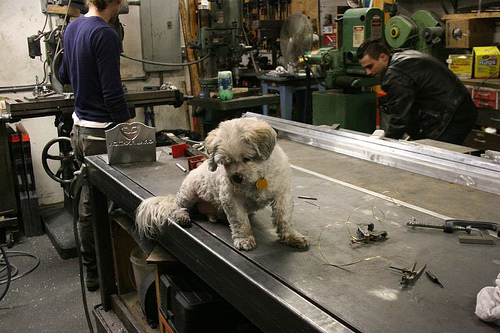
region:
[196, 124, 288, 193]
the dog is white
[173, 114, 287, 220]
the dog is sitting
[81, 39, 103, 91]
the shirt is blue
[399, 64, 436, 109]
the jacket is black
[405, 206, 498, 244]
the clamp is on the equipment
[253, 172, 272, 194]
the tag is yellow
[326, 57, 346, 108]
the equipment is green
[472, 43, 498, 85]
the box is yellow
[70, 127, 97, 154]
the pants are gray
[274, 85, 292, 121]
the leg is blue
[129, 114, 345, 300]
a dog on a table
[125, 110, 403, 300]
a dog on a metal table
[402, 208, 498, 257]
a metal vice grip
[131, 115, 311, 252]
a small white dog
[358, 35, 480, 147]
a man wearing a leather jacket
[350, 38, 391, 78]
a man with short hair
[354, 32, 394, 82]
a man with black hair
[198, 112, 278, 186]
the head of a dog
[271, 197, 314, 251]
the front leg of a dog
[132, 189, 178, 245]
the tail of a dog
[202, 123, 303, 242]
a dog with a hair cut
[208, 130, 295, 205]
a dog with a gold collar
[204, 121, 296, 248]
a dog looking down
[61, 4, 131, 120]
a person with a purple shirt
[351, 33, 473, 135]
a man leaning down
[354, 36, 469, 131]
a man with a black jacket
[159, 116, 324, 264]
a dog sitting on a table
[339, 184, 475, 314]
work tools on a table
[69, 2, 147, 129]
a man facing right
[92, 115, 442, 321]
a small dog on a table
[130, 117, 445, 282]
a small dog on a metal table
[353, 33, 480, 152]
a man wearing a black leather jacket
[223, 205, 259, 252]
the leg of a dog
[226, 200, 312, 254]
the front legs of a dog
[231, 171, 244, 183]
the nose of a dog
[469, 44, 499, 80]
A square yellow box.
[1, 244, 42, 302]
Grey cords on the floor.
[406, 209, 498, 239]
A tool on the counter.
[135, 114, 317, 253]
A white puppy sitting.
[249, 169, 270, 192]
A round dog collar.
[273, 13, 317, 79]
A electric house fan.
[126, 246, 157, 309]
A white bucket under the counter.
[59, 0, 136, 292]
A person standing wearing a blue shirt.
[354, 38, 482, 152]
A man wearing a black jacket.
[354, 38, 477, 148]
A man wearing black pants.